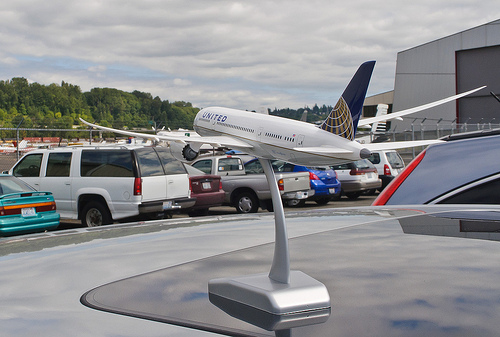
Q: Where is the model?
A: On stand.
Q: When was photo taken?
A: Daytime.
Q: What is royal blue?
A: A car.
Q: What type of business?
A: Airport.